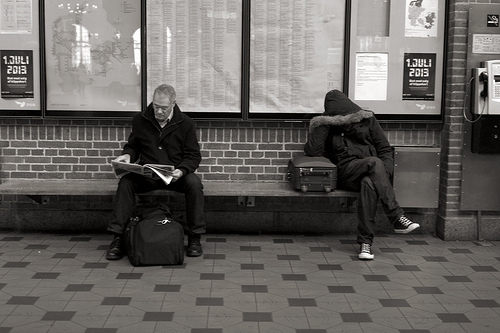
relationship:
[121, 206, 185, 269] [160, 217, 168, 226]
bag has zipper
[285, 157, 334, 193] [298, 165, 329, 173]
suitcase has zipper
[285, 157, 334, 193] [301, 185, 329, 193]
suitcase has wheels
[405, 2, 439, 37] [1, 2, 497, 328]
map for a terminal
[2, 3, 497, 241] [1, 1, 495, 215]
wall made of bricks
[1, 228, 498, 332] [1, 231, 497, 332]
tiles are in a pattern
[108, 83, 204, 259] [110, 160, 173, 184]
man reading newspaper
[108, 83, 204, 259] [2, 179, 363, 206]
man sitting on bench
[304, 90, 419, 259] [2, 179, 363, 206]
person sitting on bench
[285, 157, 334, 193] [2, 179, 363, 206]
suitcase on bench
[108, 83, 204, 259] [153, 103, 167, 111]
man wearing glasses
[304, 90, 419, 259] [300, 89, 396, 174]
person has on jacket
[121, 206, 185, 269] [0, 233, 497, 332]
bag on floor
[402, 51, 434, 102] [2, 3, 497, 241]
poster on wall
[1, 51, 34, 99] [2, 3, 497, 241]
poster on wall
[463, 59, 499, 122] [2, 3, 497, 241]
phone on wall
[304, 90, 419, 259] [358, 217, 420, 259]
person wearing shoes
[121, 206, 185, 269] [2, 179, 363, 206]
bag under bench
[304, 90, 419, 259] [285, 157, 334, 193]
person leaning on suitcase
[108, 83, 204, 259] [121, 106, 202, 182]
man has on peacoat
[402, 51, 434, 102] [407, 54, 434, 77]
poster has writing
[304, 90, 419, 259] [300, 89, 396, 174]
person has jacket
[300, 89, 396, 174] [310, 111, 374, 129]
jacket has fur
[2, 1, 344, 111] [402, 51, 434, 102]
window has poster